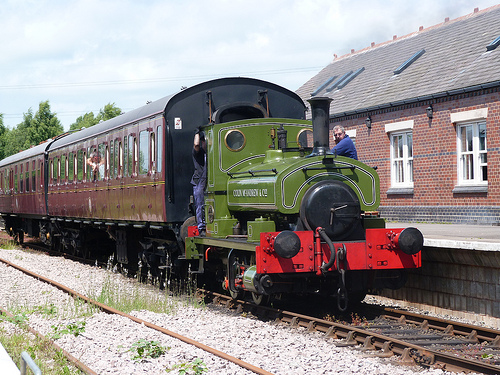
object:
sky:
[0, 0, 499, 133]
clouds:
[0, 0, 499, 131]